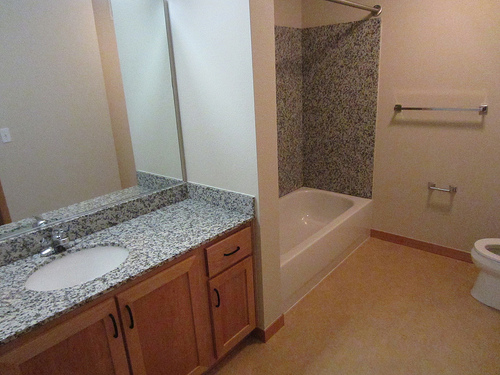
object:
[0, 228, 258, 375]
drawers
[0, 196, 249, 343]
counters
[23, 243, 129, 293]
sink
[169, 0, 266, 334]
wall surface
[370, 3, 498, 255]
wall surface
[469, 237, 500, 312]
toilet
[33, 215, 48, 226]
reflection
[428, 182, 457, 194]
handle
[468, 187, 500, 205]
ground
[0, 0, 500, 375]
bathroom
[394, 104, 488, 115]
handle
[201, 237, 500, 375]
floor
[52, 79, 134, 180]
reflects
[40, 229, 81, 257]
tap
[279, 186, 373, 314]
basin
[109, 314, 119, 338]
handles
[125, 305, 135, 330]
handles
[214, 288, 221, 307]
handles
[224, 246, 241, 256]
handles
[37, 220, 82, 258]
faucet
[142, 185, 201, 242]
surface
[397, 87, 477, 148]
towel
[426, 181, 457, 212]
paper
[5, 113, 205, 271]
handwash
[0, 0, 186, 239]
mirror